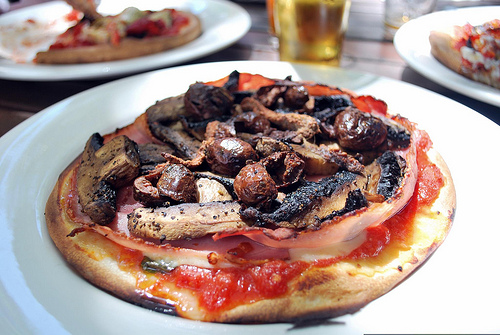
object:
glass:
[266, 0, 348, 70]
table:
[5, 3, 495, 110]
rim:
[3, 58, 223, 79]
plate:
[1, 58, 499, 333]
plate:
[0, 0, 252, 82]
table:
[1, 0, 498, 135]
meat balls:
[83, 76, 423, 246]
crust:
[44, 151, 456, 321]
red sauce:
[175, 207, 429, 310]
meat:
[89, 133, 146, 189]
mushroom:
[76, 132, 140, 224]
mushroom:
[128, 199, 255, 243]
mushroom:
[240, 150, 407, 229]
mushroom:
[334, 106, 386, 152]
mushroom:
[208, 136, 259, 173]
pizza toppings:
[70, 69, 417, 268]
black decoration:
[288, 189, 321, 213]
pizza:
[50, 72, 452, 325]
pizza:
[432, 12, 499, 82]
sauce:
[178, 257, 314, 309]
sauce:
[346, 175, 423, 262]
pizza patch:
[164, 257, 306, 307]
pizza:
[26, 3, 204, 66]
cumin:
[127, 201, 240, 239]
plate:
[393, 5, 497, 105]